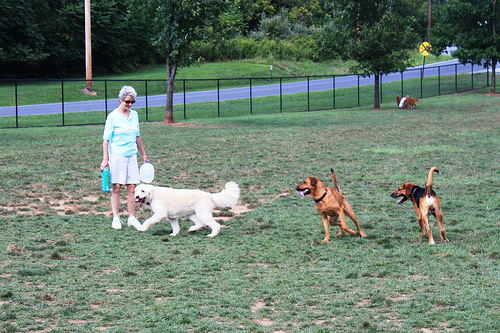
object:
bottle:
[138, 163, 156, 184]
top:
[143, 160, 151, 163]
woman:
[98, 85, 149, 230]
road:
[0, 54, 499, 118]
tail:
[210, 180, 240, 209]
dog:
[132, 181, 240, 238]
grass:
[0, 85, 499, 331]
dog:
[293, 167, 368, 243]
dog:
[388, 166, 449, 246]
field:
[0, 51, 499, 333]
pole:
[84, 0, 92, 93]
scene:
[0, 86, 499, 332]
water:
[138, 161, 155, 184]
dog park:
[0, 86, 499, 332]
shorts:
[106, 154, 141, 187]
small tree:
[138, 0, 213, 124]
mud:
[164, 112, 173, 124]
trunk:
[163, 80, 176, 123]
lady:
[99, 84, 150, 230]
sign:
[417, 41, 432, 58]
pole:
[420, 55, 426, 78]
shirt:
[101, 107, 140, 157]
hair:
[117, 85, 139, 104]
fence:
[0, 58, 499, 130]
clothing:
[101, 106, 140, 156]